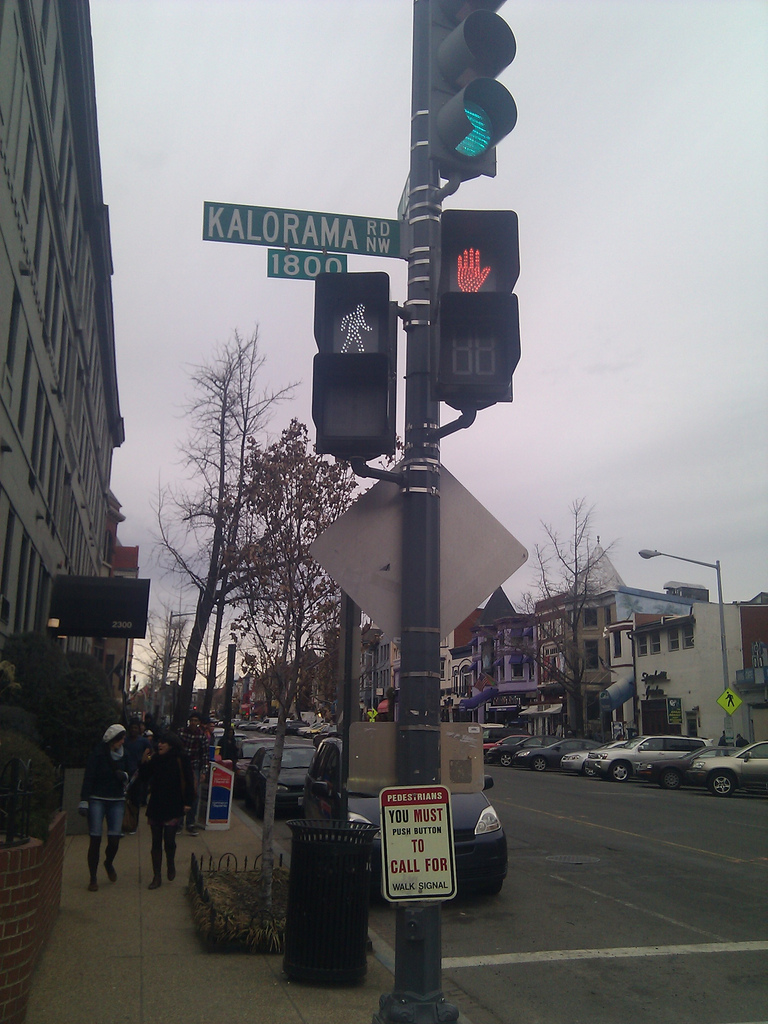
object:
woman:
[72, 718, 136, 893]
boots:
[87, 856, 99, 887]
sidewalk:
[33, 837, 240, 1021]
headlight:
[349, 808, 379, 840]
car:
[690, 736, 735, 777]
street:
[344, 751, 761, 1011]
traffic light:
[448, 201, 520, 291]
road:
[451, 774, 756, 1009]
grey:
[500, 718, 759, 1024]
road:
[448, 844, 755, 1024]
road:
[423, 737, 748, 967]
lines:
[632, 777, 729, 894]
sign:
[272, 247, 348, 274]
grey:
[456, 770, 740, 972]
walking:
[79, 767, 119, 852]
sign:
[374, 786, 461, 902]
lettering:
[391, 854, 396, 870]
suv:
[591, 710, 699, 770]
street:
[468, 835, 744, 1024]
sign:
[712, 681, 746, 716]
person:
[725, 688, 738, 708]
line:
[445, 934, 768, 954]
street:
[488, 783, 663, 961]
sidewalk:
[84, 862, 197, 1012]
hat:
[104, 720, 129, 733]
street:
[529, 774, 732, 1002]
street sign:
[198, 203, 401, 263]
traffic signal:
[328, 271, 384, 363]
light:
[462, 110, 510, 150]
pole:
[716, 575, 732, 746]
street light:
[644, 543, 648, 559]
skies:
[72, 5, 764, 703]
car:
[293, 698, 508, 892]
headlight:
[478, 807, 504, 837]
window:
[510, 618, 527, 643]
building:
[448, 558, 584, 824]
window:
[510, 654, 527, 679]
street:
[331, 703, 762, 985]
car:
[485, 733, 534, 766]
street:
[347, 774, 765, 996]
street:
[305, 707, 761, 998]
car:
[253, 740, 359, 818]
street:
[306, 740, 764, 998]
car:
[691, 739, 766, 792]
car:
[514, 737, 586, 773]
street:
[298, 718, 761, 965]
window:
[586, 655, 602, 682]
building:
[560, 544, 652, 749]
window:
[647, 621, 660, 657]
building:
[623, 574, 751, 783]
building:
[21, 83, 115, 852]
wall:
[13, 553, 114, 758]